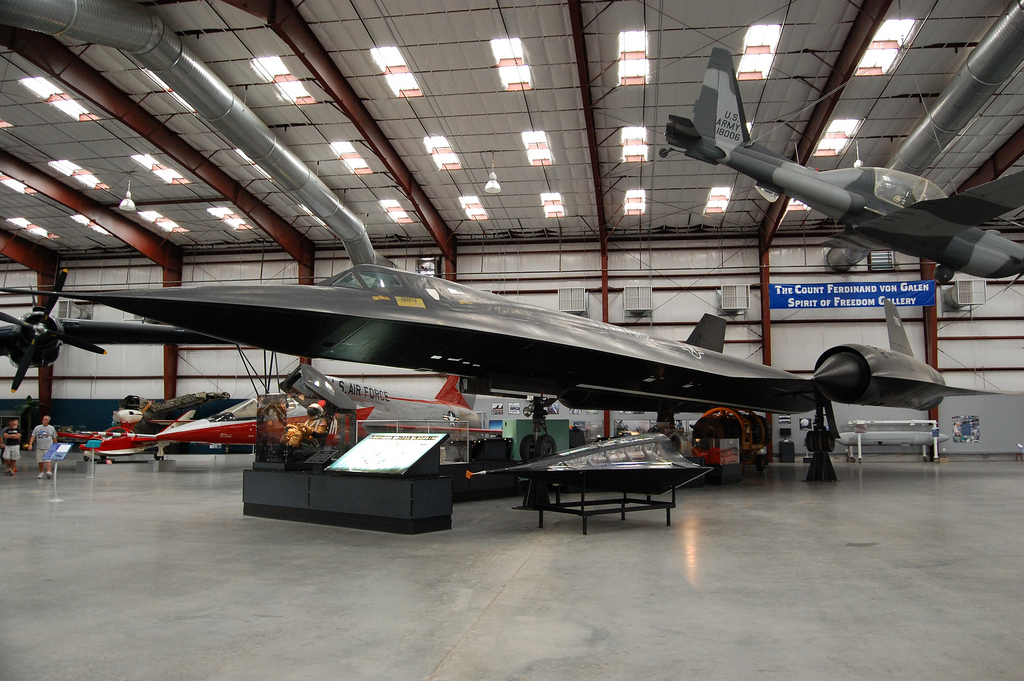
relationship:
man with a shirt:
[0, 417, 24, 453] [0, 417, 24, 453]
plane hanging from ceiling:
[663, 85, 1018, 251] [319, 85, 1018, 251]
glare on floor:
[634, 508, 755, 600] [252, 508, 755, 655]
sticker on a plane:
[382, 287, 465, 339] [382, 287, 831, 420]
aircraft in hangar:
[95, 261, 951, 530] [103, 272, 809, 544]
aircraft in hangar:
[95, 261, 951, 530] [141, 250, 866, 576]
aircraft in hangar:
[95, 261, 951, 530] [155, 260, 845, 530]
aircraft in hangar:
[95, 261, 951, 530] [21, 208, 737, 500]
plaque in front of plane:
[258, 419, 438, 528] [304, 290, 900, 468]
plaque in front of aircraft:
[313, 402, 444, 461] [95, 261, 951, 530]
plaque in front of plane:
[258, 419, 438, 528] [302, 205, 907, 518]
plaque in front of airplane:
[258, 419, 438, 528] [106, 257, 875, 495]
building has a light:
[32, 7, 1021, 322] [208, 85, 948, 273]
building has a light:
[32, 7, 1021, 322] [31, 85, 845, 297]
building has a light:
[32, 7, 1021, 322] [164, 79, 908, 301]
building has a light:
[32, 7, 1021, 322] [82, 58, 760, 236]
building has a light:
[146, 28, 883, 267] [146, 28, 883, 267]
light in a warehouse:
[353, 42, 424, 104] [71, 51, 1011, 536]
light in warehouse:
[420, 130, 466, 188] [54, 25, 1003, 665]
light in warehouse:
[334, 134, 377, 189] [54, 25, 1003, 665]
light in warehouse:
[855, 14, 917, 107] [54, 25, 1003, 665]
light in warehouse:
[818, 105, 858, 166] [82, 39, 987, 581]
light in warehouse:
[739, 26, 779, 115] [54, 25, 1003, 665]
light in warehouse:
[698, 177, 738, 228] [71, 51, 1011, 536]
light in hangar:
[12, 74, 101, 119] [3, 12, 1008, 681]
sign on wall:
[765, 276, 937, 312] [719, 237, 969, 356]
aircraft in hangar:
[94, 238, 1015, 530] [94, 238, 1015, 530]